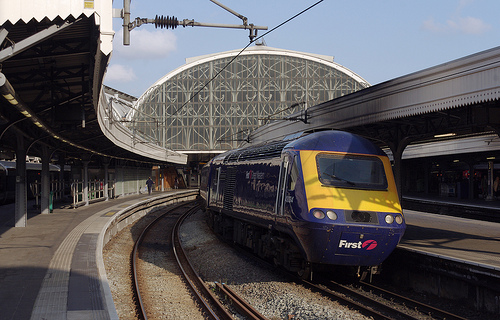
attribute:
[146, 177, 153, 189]
clothing — dark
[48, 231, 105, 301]
stone square — light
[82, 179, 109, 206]
white rails — metal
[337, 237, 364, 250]
word — white and blue, large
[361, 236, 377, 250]
logo — red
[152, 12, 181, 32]
electrical coil — metal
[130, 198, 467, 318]
tracks — metal, train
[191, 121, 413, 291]
train — blue and gold, blue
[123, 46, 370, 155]
structure — arched, ornate, metal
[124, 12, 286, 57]
pole — metal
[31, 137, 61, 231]
pole — metal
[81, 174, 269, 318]
tracks — empty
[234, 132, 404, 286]
train — blue and yellow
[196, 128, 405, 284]
train — blue and yellow, blue, yellow, passenger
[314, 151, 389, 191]
window — yellow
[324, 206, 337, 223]
headlight — small, round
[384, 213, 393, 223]
headlight — small, round